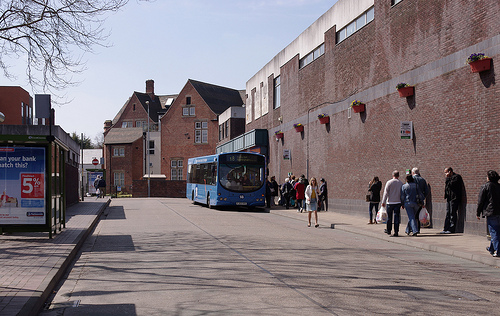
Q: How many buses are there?
A: One.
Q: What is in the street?
A: A bus.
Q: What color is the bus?
A: Blue.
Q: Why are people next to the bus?
A: To get on the bus.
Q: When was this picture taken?
A: During the day.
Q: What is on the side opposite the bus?
A: Bus stop.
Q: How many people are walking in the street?
A: One.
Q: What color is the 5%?
A: White.